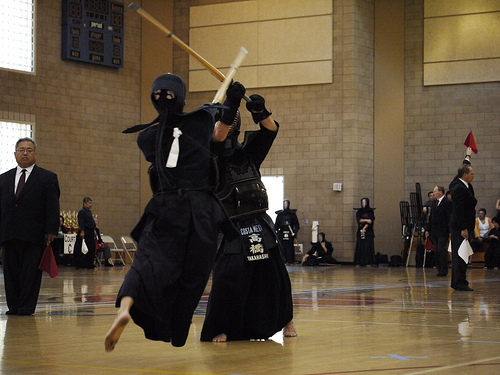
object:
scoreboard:
[61, 0, 126, 69]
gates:
[397, 182, 426, 232]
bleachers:
[406, 230, 487, 267]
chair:
[120, 236, 138, 264]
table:
[64, 233, 76, 254]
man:
[74, 197, 100, 270]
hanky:
[81, 238, 89, 255]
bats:
[126, 3, 247, 105]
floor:
[0, 262, 500, 375]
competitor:
[353, 198, 377, 268]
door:
[261, 176, 284, 225]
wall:
[0, 0, 500, 375]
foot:
[104, 315, 129, 352]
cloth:
[463, 130, 478, 155]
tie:
[16, 168, 26, 198]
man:
[449, 145, 478, 291]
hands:
[461, 228, 469, 240]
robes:
[114, 102, 293, 348]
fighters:
[104, 72, 298, 352]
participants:
[275, 197, 377, 267]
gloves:
[200, 78, 272, 125]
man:
[0, 137, 60, 317]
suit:
[0, 163, 60, 311]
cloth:
[458, 238, 474, 265]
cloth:
[38, 241, 59, 279]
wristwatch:
[465, 155, 472, 159]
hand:
[466, 146, 473, 156]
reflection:
[450, 292, 488, 343]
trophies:
[59, 210, 99, 233]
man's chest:
[1, 167, 42, 229]